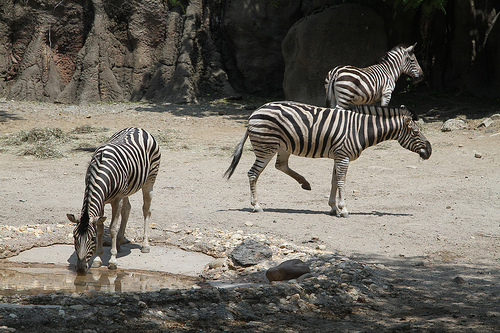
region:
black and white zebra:
[66, 126, 162, 273]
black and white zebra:
[224, 101, 434, 218]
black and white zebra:
[322, 42, 422, 107]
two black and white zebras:
[223, 41, 435, 220]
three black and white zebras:
[69, 44, 434, 273]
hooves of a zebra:
[91, 254, 118, 269]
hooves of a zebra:
[327, 201, 348, 216]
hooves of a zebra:
[250, 181, 349, 219]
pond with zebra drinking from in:
[1, 127, 198, 299]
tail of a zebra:
[222, 130, 250, 182]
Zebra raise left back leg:
[219, 89, 445, 228]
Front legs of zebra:
[325, 157, 357, 229]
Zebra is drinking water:
[28, 114, 185, 292]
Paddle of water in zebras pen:
[8, 256, 201, 312]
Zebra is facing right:
[316, 36, 442, 113]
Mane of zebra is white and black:
[333, 91, 414, 123]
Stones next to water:
[228, 224, 308, 282]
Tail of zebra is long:
[214, 116, 254, 186]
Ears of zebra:
[394, 101, 421, 128]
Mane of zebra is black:
[74, 211, 93, 241]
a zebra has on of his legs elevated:
[231, 96, 441, 226]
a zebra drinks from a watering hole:
[68, 110, 176, 286]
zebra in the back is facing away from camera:
[315, 41, 425, 108]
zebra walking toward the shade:
[303, 29, 430, 114]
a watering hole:
[0, 249, 235, 309]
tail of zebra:
[213, 124, 250, 175]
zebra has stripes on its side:
[265, 106, 373, 162]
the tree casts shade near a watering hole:
[26, 241, 468, 328]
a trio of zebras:
[44, 28, 460, 276]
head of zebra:
[396, 106, 443, 172]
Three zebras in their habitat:
[34, 12, 487, 309]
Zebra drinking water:
[26, 97, 202, 295]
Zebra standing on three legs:
[210, 82, 452, 224]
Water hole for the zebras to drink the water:
[0, 250, 225, 307]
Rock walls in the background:
[2, 2, 256, 104]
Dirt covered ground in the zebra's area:
[274, 218, 497, 327]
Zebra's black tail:
[217, 115, 256, 195]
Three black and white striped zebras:
[46, 35, 444, 292]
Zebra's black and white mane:
[345, 95, 421, 127]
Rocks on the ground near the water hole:
[202, 225, 357, 305]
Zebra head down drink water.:
[69, 121, 151, 287]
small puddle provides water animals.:
[3, 251, 248, 312]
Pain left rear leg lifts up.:
[224, 89, 448, 222]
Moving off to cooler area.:
[319, 33, 428, 105]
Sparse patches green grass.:
[6, 104, 98, 166]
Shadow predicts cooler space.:
[142, 3, 318, 115]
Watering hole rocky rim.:
[5, 244, 315, 327]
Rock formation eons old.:
[8, 4, 223, 109]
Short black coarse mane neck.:
[76, 165, 96, 243]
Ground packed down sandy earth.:
[361, 144, 498, 276]